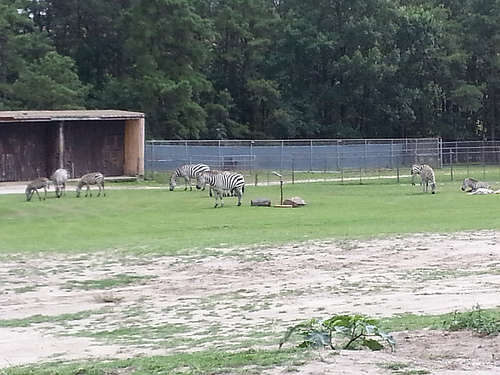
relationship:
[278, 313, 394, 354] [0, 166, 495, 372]
plant sticking out of ground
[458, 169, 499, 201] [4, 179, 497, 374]
zebra on field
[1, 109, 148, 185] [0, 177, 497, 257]
wooden shed behind grass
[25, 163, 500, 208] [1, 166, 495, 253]
zebra grazing in pasture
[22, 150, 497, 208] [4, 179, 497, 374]
group on field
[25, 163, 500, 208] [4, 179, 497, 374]
zebra on field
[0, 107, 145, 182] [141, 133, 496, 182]
structure by fence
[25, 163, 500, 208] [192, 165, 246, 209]
zebra grazing in zebra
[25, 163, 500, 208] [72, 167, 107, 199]
zebra grazing in zebra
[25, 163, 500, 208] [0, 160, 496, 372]
zebra grazing in pasture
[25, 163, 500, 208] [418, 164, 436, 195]
zebra grazing in zebra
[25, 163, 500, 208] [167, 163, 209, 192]
zebra grazing in zebra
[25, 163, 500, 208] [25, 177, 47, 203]
zebra grazing in zebra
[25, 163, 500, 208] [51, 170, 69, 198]
zebra grazing in zebra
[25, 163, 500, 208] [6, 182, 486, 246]
zebra grazing in pasture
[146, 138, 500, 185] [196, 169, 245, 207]
fence around zebra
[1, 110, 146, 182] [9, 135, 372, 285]
wooden shed in zebra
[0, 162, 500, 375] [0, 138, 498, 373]
grass in exhibit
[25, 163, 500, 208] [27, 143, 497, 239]
zebra grazing in field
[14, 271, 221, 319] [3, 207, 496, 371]
dirt on ground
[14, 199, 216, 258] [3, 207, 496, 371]
grass on ground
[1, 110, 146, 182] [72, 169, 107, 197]
wooden shed by zebra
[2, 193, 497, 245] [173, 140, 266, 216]
field with zebra'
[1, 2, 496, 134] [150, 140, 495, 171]
green trees behind fence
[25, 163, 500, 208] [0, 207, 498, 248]
zebra grazing on grass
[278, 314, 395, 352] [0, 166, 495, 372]
plant growing from ground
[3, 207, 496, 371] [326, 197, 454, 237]
ground filled with grass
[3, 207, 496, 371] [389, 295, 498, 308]
ground filled with dirt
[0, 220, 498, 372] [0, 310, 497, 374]
patches on grass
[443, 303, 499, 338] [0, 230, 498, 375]
leaves on dirt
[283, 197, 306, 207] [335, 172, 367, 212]
rocks in middle of grass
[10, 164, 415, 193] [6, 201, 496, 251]
dirt path next to grass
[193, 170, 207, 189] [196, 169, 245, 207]
head of zebra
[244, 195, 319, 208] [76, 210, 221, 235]
rocks in field